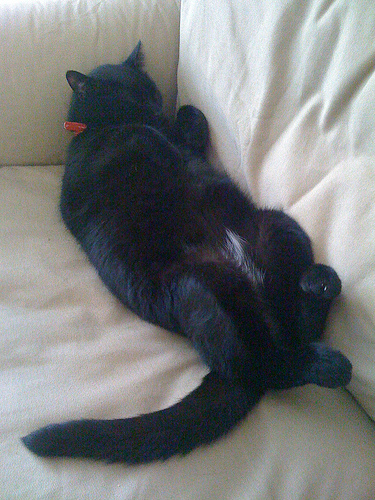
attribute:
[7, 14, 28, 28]
scene — outdoors 